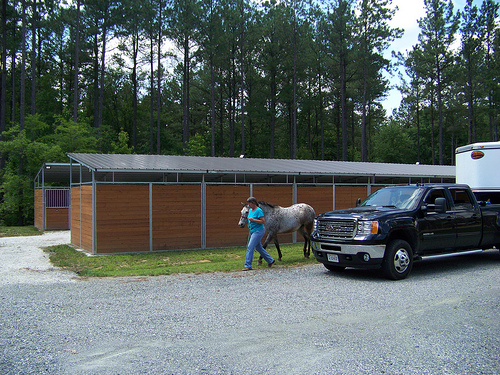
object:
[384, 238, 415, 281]
tire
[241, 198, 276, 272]
man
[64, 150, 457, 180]
roof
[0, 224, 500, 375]
ground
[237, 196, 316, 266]
horse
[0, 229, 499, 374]
gravel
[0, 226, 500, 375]
road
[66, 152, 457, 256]
pens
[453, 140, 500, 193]
trailer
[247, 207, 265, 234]
shirt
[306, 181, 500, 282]
truck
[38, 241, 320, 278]
grassy area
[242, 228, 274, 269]
blue jeans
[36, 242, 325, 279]
grass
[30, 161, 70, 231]
horse pen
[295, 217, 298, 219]
spots